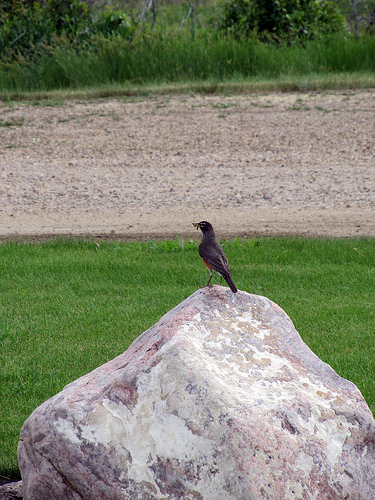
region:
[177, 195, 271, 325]
a bird on a rock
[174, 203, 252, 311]
a black and red bird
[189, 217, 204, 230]
small black beak on bird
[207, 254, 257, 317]
long black tail feathers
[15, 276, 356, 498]
a large white and gray rock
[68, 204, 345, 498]
large rock with bird on top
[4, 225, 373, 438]
green grass on the ground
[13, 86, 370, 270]
a dirt road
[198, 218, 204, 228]
small black eye of bird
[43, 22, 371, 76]
tall grass across the street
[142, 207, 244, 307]
the bird has something in his mouth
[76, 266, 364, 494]
the rock is big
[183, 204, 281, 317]
the bird is dark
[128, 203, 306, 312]
the bird is black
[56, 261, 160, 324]
the grass is dark green mixed with light green.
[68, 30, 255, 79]
the grass is tall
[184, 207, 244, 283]
there is a worm in the birds mouth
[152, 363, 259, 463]
the rock is white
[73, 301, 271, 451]
the rock is different shaped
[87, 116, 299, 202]
the small gravel rocks are in the background.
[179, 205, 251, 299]
black bird on rock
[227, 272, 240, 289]
black tail on bird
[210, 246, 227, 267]
black feather on bird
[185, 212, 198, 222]
black beak on bird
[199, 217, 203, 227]
black eye on bird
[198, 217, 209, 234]
left eye on bird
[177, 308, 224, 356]
white speck on rock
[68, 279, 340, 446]
large rock on ground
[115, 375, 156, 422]
brown speck on rock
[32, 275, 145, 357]
green grass on ground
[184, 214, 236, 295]
black bird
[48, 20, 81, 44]
green leaves in brown tree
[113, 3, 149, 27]
green leaves in brown tree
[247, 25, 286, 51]
green leaves in brown tree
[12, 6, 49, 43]
green leaves in brown tree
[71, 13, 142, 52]
green leaves in brown tree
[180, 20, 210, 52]
green leaves in brown tree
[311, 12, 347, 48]
green leaves in brown tree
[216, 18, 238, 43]
green leaves in brown tree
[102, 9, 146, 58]
green leaves in brown tree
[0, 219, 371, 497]
Small bird perched on a rock.